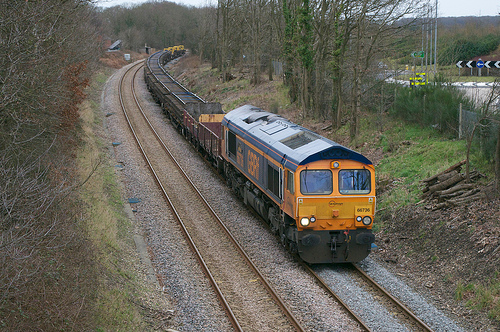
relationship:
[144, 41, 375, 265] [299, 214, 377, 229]
train has headlights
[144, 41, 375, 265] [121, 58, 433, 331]
train on tracks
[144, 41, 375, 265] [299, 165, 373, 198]
train has windshield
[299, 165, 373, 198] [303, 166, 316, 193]
windshield has wiper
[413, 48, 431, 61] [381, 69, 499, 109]
sign on highway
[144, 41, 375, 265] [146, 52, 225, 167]
train has cars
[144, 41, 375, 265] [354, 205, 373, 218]
train has number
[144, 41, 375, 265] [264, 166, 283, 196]
train has window